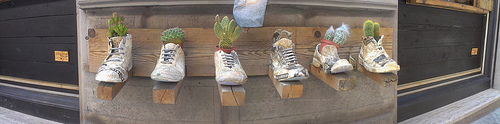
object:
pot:
[215, 44, 237, 52]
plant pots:
[212, 45, 248, 86]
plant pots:
[356, 35, 403, 74]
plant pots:
[308, 38, 354, 73]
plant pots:
[266, 42, 308, 80]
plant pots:
[148, 44, 184, 84]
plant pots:
[94, 34, 133, 83]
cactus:
[313, 22, 351, 47]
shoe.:
[357, 37, 399, 73]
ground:
[0, 91, 500, 124]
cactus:
[105, 12, 134, 39]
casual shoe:
[312, 38, 354, 74]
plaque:
[54, 51, 69, 63]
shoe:
[90, 34, 133, 83]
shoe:
[214, 48, 248, 86]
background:
[0, 0, 497, 124]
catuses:
[361, 19, 382, 42]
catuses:
[268, 29, 294, 51]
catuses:
[215, 15, 244, 47]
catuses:
[161, 26, 184, 50]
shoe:
[311, 39, 355, 74]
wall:
[0, 0, 500, 124]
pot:
[348, 53, 400, 83]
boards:
[0, 0, 79, 95]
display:
[84, 12, 402, 107]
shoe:
[150, 42, 185, 83]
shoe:
[265, 44, 308, 82]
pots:
[93, 12, 137, 84]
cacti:
[94, 11, 134, 101]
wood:
[95, 54, 397, 106]